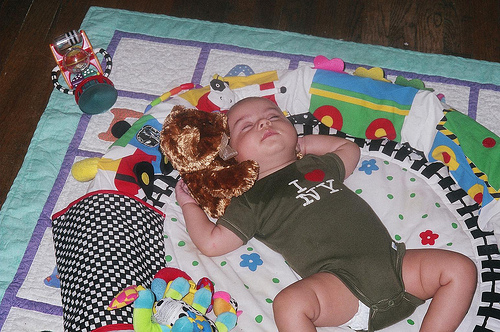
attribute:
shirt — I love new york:
[214, 157, 413, 330]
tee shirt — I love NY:
[232, 168, 401, 301]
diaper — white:
[347, 297, 369, 330]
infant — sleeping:
[93, 57, 499, 330]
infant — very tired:
[230, 100, 433, 330]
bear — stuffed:
[159, 102, 223, 175]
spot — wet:
[247, 167, 298, 193]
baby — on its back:
[172, 94, 482, 330]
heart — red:
[304, 164, 329, 189]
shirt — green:
[208, 149, 423, 329]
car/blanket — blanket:
[103, 128, 162, 203]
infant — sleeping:
[161, 123, 493, 324]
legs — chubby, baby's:
[273, 248, 482, 329]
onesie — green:
[219, 151, 430, 327]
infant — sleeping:
[150, 80, 473, 329]